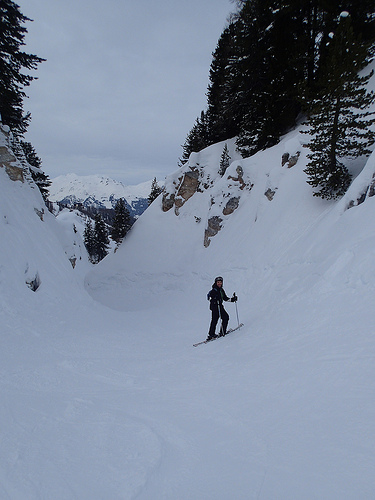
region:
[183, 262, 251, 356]
Person standing on skis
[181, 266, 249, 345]
Person holding ski poles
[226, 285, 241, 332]
Long metal ski pole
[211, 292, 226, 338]
Long metal ski pole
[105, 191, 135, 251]
Medium sized evergreen tree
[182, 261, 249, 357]
Person standing in the snow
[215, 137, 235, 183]
Small evergreen tree on the side of a hill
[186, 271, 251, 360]
Person wearing all black clothing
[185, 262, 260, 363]
Person standing in a snow covered gulley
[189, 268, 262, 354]
Person on skis wearing black clothing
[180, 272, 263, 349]
a man on a ski slope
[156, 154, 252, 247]
rocks sticking out of the snow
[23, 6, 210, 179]
a cloudy overcast sky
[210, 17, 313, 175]
pine trees on the side of a mountain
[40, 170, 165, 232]
snow capped mountains in the background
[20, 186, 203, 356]
a valley of snow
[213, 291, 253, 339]
a man's ski poles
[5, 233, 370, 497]
a large patch of white snow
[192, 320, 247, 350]
a man's skis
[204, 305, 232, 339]
a man's black snow pants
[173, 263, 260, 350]
a person skiing on a tall slope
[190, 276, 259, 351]
a person holding two ski poles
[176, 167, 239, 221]
large boulders jutting out of the snow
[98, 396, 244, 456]
cold icy white snow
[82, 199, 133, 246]
pine trees growing in the valley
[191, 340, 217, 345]
skis attached to feet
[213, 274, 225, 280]
a black hat warming a head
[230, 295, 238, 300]
a hand grasping a pole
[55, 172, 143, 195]
a snow covered mountain in the distance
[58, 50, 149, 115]
an overcast gray sky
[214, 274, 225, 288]
the head of a person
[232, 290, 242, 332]
a ski pole in the person's hand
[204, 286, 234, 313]
a black coat on the person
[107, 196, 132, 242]
a green tree in the background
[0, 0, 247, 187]
a gray sky over the mountain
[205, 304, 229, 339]
a pair of black pants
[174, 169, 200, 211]
a large brown rock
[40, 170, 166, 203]
snow covered mountains in the distance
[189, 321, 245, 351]
a pair of skis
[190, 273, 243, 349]
a person skiing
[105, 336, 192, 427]
the snow is white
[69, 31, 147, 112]
the sky is white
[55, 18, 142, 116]
the sky is cloudy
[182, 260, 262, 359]
the man is skiing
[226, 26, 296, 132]
the trees are tall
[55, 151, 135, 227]
the mountain is tall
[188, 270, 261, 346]
the person is standing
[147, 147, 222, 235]
the rocks are large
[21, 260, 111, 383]
the snow is thick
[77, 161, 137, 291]
the trees are far